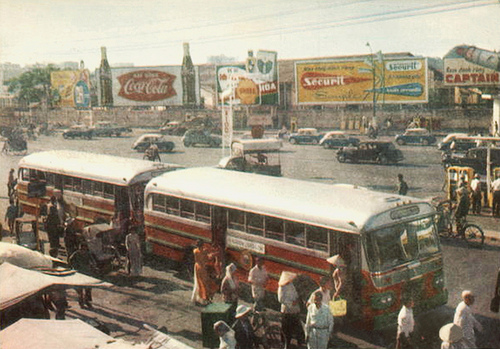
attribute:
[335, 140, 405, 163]
car — black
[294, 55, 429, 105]
billboard — orange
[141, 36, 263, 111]
bottle — large, brown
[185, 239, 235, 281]
woman — white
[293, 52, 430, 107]
billboard — huge, yellow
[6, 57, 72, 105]
tree — tall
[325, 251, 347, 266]
hat — chinese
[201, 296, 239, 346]
trash bin — green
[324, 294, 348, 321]
purse — yellow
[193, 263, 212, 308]
dress — orange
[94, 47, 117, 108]
bottle — large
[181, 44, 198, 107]
bottle — large